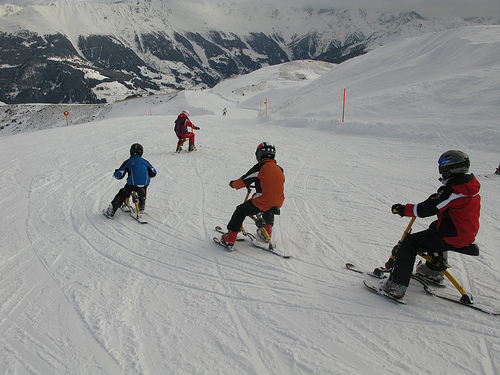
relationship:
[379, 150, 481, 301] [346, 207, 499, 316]
boy on skis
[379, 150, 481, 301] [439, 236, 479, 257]
boy on seat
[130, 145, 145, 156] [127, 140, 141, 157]
helmet on head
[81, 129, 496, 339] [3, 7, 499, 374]
stripes in snow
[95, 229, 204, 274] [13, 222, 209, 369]
tracks on snow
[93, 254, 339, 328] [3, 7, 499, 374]
marks on snow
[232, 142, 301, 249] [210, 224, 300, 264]
boy on skis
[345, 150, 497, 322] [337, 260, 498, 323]
boy on skis